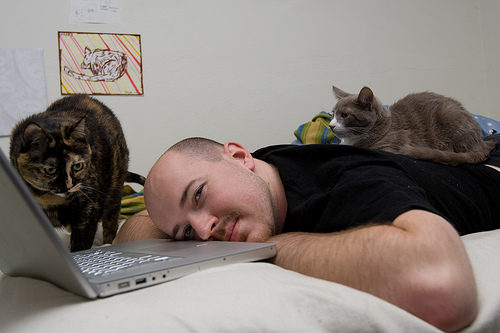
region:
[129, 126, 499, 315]
man laying on bed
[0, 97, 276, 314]
silver open lap top on bed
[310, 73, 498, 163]
cat laying on mans back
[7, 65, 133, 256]
cat standing on bed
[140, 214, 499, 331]
white comforter on bed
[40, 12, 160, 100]
picture of cat on the wall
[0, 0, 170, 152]
pictures on the wall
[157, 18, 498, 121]
white covered wall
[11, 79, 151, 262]
cat looking at lap top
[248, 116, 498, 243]
man wearing black shirt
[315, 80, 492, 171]
Grey cat with white face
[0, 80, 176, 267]
Calico cat standing on bed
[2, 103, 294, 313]
Silver computer open on bed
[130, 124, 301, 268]
Bald head with eyes and mouth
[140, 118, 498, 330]
Man with cat lying on back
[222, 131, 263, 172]
Pink human ear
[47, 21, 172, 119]
Drawing of cat hanging on wall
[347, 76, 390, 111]
Furry grey cat ear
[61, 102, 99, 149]
Furry calico cat ear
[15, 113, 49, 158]
Furry calico cat ear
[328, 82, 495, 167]
a grey cat laying down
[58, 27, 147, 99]
a picture on the wall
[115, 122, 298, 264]
a man resting his face on a laptop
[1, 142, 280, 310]
a silver laptop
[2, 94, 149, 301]
a cat looking at the laptop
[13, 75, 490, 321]
two cats and a man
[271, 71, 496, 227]
a cat laying on the mans back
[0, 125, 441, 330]
silver laptop sitting on a pillow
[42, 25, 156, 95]
a picture of a cat on the wall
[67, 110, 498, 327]
a man laying in bed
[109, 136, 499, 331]
man in black t-shirt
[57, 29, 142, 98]
drawing of cat on wall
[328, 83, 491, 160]
gray and white cat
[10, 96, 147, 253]
calico cat on bed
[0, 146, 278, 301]
open silver laptop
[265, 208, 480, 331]
man's hairy forearm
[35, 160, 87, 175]
cat's yellow and black eyes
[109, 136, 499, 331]
man with shaved head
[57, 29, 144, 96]
picture with brown and pink stripes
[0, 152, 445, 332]
laptop on white pillow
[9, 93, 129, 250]
The dark cat is splotchy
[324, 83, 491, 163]
The greyish cat is comfy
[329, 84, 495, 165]
The cat has a white muzzle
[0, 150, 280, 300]
A silver laptop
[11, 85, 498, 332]
A man is lying with his cats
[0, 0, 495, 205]
A colorful picture is on the wall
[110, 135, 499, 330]
A man in a black shirt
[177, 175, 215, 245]
Blue eyes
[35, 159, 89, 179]
The calico cat's yellow eyes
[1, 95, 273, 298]
The calico cat is next to the laptop